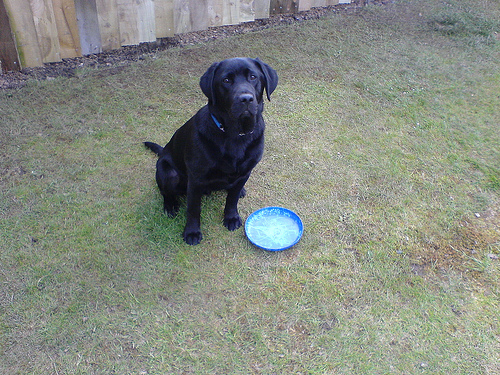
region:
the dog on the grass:
[112, 48, 272, 236]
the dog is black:
[140, 45, 270, 240]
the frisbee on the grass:
[230, 200, 315, 275]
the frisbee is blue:
[233, 197, 297, 257]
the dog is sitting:
[126, 56, 276, 236]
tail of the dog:
[122, 134, 160, 153]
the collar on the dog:
[193, 103, 236, 140]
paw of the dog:
[175, 211, 207, 248]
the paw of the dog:
[218, 200, 253, 238]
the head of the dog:
[194, 41, 285, 121]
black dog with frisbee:
[39, 9, 381, 311]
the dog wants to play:
[76, 0, 358, 289]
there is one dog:
[59, 20, 344, 281]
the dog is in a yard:
[46, 20, 388, 347]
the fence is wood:
[48, 12, 158, 76]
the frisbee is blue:
[231, 209, 326, 287]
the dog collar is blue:
[91, 12, 353, 319]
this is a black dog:
[106, 8, 353, 320]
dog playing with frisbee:
[110, 33, 352, 284]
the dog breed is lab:
[93, 29, 340, 285]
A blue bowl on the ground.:
[241, 205, 302, 250]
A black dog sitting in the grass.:
[141, 55, 276, 245]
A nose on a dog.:
[235, 86, 251, 101]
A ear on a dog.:
[250, 55, 275, 100]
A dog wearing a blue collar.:
[140, 55, 275, 245]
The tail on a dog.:
[135, 135, 160, 150]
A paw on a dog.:
[180, 180, 205, 245]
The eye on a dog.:
[245, 68, 259, 84]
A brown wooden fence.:
[4, 0, 281, 70]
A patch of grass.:
[431, 6, 496, 42]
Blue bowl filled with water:
[243, 205, 305, 250]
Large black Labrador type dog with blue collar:
[140, 52, 279, 243]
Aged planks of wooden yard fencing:
[15, 0, 105, 72]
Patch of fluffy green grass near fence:
[433, 5, 491, 43]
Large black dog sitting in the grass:
[139, 54, 276, 250]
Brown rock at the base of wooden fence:
[17, 53, 97, 80]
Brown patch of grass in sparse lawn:
[408, 220, 498, 281]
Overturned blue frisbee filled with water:
[242, 203, 306, 253]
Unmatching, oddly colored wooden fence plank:
[70, 0, 113, 61]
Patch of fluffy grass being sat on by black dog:
[140, 171, 238, 251]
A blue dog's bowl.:
[241, 203, 304, 251]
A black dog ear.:
[197, 58, 229, 105]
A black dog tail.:
[139, 138, 164, 155]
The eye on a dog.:
[218, 70, 235, 88]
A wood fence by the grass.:
[3, 0, 391, 70]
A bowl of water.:
[241, 206, 305, 251]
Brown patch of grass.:
[436, 222, 499, 280]